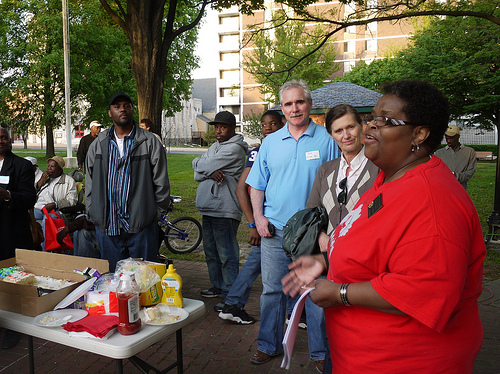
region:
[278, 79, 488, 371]
a woman wearing a red shirt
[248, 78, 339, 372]
a man wearing a blue shirt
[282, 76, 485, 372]
a woman wearing glasses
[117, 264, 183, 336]
ketchup and mustard bottles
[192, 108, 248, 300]
a man crossing his arms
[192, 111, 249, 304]
a man wearing a gray sweatshirt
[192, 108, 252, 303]
a man wearing a hat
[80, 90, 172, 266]
a man wearing a striped shirt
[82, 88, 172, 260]
a man wearing a black hat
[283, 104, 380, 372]
a woman holding a jacket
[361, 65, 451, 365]
A woman wearing a red shirt.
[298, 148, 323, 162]
A name tag on a shirt.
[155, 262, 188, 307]
A bottle of mustard.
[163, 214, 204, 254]
Bicycle wheel behind the crowd.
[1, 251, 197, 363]
A table covered with food items.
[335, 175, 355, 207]
Sunglasses hanging from a woman's shirt.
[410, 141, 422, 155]
Silver loop earrings.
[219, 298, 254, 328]
Black and white tennis shoe.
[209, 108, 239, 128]
A black baseball hat.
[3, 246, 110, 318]
A cardboard box sitting on a table.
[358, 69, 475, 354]
A woman is wearing a red short sleeved shirt.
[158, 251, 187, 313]
There is a squeeze bottle of mustard on the table.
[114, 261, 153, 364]
There is a plastic bottle of ketchup on the table.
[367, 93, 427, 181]
The woman is wearing eye glasses.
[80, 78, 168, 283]
A man is watching the woman.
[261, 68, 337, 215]
This man is wearing a name tag.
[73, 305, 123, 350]
There are red napkins on the table.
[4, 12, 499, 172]
The picture is taken outside during the day.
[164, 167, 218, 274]
There is a blue bicycle partially showing behind a man.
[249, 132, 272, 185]
The number 3 is showing on the sleeve of a shirt.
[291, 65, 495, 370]
A woman standing with red shirt on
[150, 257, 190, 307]
A bottle of mustard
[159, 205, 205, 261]
A bicycle tire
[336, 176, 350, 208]
pair of black sunglasses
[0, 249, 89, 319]
Cake in a box half gone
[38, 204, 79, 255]
A red reusable bag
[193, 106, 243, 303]
A man standing arms crossed with black cap on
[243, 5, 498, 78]
A long skinny tree branch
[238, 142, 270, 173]
A white number 3 on a blue shirt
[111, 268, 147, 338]
A bottle of ketchup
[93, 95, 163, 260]
an african american male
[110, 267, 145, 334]
a bottle of ketchup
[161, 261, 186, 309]
a bottle of mustard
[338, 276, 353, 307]
a bracelet worn by a woman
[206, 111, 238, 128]
a black hat on top of man's head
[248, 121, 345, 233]
a blue shirt worn by a man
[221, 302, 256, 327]
a black and white shoe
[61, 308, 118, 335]
red napkins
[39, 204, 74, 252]
a reed tote bag